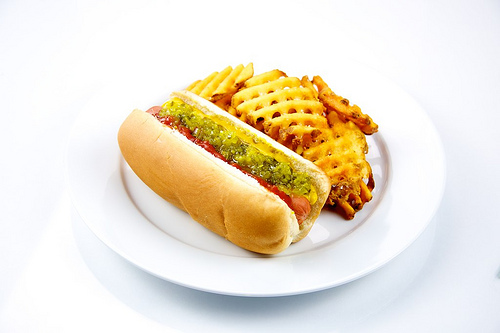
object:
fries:
[186, 62, 378, 221]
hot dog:
[117, 89, 330, 256]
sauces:
[160, 96, 321, 207]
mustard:
[160, 97, 320, 206]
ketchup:
[151, 113, 293, 207]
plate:
[81, 58, 446, 300]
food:
[117, 62, 378, 256]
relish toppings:
[151, 112, 295, 210]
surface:
[0, 1, 499, 329]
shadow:
[119, 254, 366, 318]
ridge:
[134, 90, 331, 232]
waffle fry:
[230, 75, 327, 147]